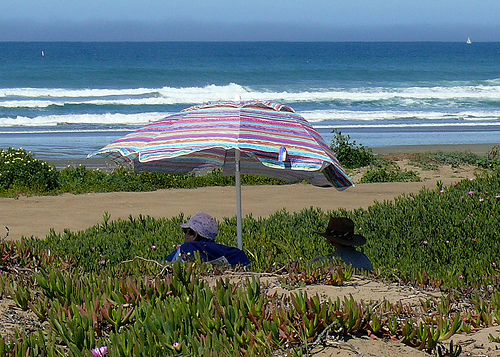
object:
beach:
[2, 136, 495, 348]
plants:
[0, 132, 422, 189]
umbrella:
[93, 98, 355, 276]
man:
[300, 214, 375, 281]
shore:
[85, 94, 362, 191]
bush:
[0, 140, 59, 197]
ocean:
[5, 4, 499, 129]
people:
[162, 209, 252, 268]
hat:
[315, 213, 367, 251]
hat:
[180, 211, 222, 240]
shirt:
[167, 242, 247, 267]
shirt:
[315, 248, 373, 275]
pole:
[233, 148, 249, 261]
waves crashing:
[3, 82, 498, 137]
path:
[5, 185, 433, 239]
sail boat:
[462, 33, 474, 45]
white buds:
[4, 144, 31, 165]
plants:
[2, 174, 499, 352]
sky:
[3, 4, 499, 27]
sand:
[399, 144, 497, 174]